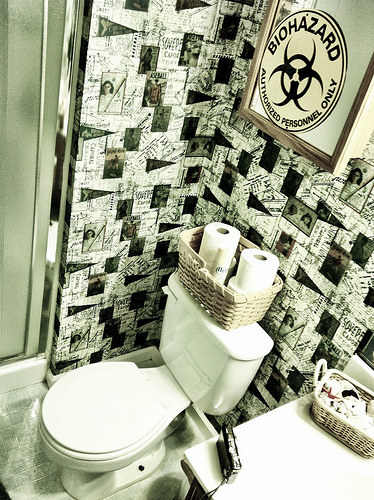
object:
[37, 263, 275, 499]
toilet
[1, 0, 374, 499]
bathroom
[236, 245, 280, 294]
toilet paper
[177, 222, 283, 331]
basket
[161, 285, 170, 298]
handle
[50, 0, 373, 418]
wallpaper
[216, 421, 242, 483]
camera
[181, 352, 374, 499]
counter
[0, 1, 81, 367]
door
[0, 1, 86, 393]
shower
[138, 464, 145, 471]
bolt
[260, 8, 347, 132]
picture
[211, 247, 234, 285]
can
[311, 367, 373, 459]
basket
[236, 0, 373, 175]
mirror